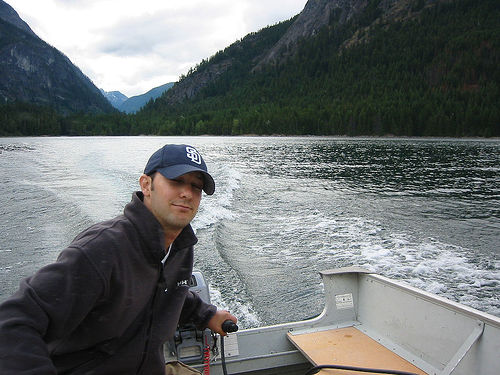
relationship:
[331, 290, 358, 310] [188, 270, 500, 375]
socket on boat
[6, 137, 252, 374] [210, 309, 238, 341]
man has hand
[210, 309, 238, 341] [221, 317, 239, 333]
hand on object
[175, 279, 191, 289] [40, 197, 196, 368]
label on jacket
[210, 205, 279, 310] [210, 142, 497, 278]
waves in water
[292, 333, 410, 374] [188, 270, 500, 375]
bench in boat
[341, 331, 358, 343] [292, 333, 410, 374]
spot on bench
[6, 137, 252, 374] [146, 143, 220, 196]
man wears cap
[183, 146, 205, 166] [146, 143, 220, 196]
logo on cap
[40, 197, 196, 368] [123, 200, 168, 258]
jacket has collar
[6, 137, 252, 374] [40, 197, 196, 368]
man wears jacket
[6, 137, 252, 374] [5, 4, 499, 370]
person in photo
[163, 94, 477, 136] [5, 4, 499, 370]
trees in photo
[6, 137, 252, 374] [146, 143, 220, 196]
man has cap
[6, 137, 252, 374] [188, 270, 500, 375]
man rides in boat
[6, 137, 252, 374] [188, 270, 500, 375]
man enjoys boat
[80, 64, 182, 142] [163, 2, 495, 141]
valley between mountains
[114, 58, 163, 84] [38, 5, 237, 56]
clouds in sky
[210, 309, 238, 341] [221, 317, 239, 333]
hand grips handle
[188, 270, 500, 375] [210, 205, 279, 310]
boat made waves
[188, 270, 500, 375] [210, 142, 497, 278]
boat races along lake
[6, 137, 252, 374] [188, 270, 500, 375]
man in boat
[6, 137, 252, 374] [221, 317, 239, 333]
man holds handle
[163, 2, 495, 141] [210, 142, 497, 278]
mountains behind water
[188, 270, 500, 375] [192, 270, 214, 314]
boat has engine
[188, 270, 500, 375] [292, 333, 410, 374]
boat has sits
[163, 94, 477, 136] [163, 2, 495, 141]
trees in background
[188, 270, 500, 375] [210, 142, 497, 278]
boat forms water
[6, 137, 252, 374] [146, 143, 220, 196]
man wears hat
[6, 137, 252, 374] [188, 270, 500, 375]
man drives boat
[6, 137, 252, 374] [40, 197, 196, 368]
man wears sweater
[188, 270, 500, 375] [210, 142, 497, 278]
boat floats in water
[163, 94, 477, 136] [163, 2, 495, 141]
trees along mountains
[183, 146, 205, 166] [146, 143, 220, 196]
logo on hat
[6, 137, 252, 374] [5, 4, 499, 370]
man in picture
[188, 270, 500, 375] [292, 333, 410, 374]
boat has bench